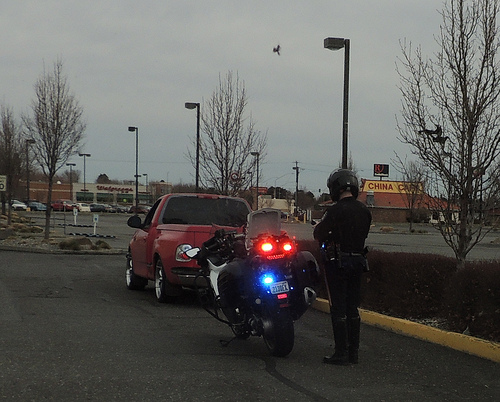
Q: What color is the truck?
A: Red.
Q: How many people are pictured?
A: One.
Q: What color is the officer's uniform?
A: Black.